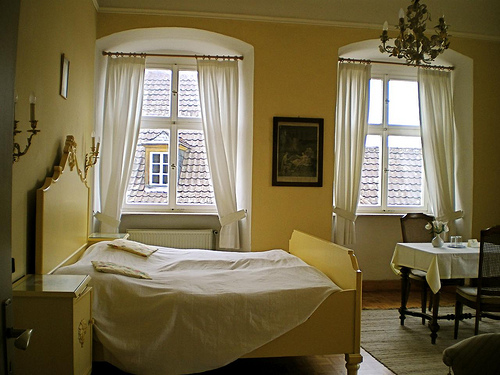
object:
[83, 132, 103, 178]
light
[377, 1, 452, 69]
light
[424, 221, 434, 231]
rose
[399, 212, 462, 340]
chair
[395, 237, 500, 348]
table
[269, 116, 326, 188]
picture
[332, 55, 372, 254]
curtain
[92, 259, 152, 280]
pillow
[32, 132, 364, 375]
bed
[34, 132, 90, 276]
headboard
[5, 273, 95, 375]
end table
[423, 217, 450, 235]
flowers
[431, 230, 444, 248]
vase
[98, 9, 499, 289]
wall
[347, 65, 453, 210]
window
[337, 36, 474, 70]
moulding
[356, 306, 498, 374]
rug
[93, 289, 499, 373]
floor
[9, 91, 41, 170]
sconse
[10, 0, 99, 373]
wall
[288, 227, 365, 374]
footboard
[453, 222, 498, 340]
chair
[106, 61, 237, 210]
window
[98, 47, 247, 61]
rod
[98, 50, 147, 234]
drape